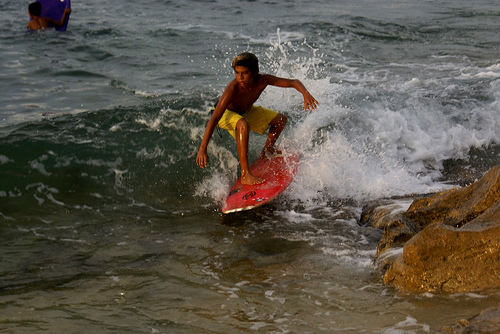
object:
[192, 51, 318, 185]
boy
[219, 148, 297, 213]
surfboard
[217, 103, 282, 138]
shorts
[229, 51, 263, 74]
hair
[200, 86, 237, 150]
arm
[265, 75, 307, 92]
arm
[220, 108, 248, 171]
legs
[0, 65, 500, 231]
wave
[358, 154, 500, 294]
boulder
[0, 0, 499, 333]
ocean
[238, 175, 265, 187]
feet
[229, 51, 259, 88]
head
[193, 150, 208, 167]
hand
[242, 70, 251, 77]
eye